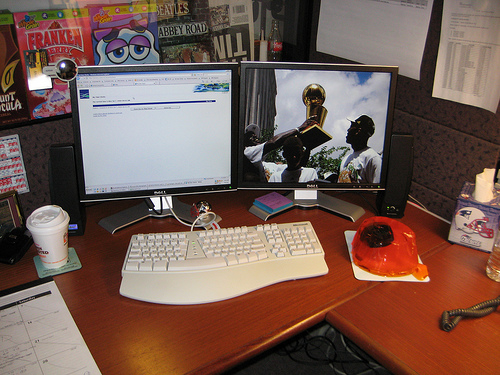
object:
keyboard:
[118, 219, 330, 307]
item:
[350, 215, 430, 281]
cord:
[439, 296, 500, 334]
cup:
[25, 204, 73, 271]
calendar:
[1, 273, 109, 374]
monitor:
[75, 63, 235, 198]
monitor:
[235, 67, 391, 188]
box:
[13, 6, 94, 125]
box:
[84, 2, 163, 71]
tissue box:
[446, 167, 499, 255]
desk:
[0, 186, 500, 374]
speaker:
[44, 138, 94, 237]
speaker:
[374, 127, 420, 220]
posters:
[157, 0, 218, 68]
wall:
[278, 1, 500, 226]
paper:
[430, 0, 500, 116]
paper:
[313, 0, 433, 82]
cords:
[324, 334, 381, 374]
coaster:
[29, 245, 85, 280]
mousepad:
[343, 226, 431, 286]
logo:
[459, 208, 475, 219]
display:
[2, 1, 255, 130]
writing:
[0, 289, 95, 374]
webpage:
[81, 76, 229, 189]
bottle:
[485, 219, 500, 285]